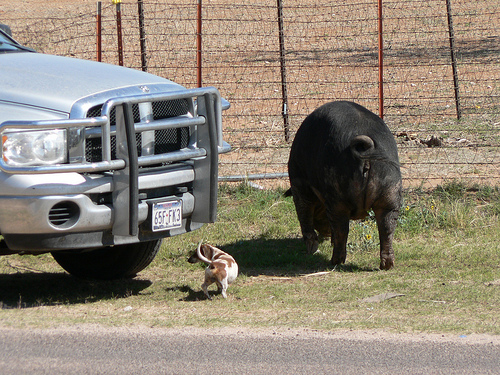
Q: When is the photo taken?
A: Daytime.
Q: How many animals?
A: Two.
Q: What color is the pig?
A: Black.